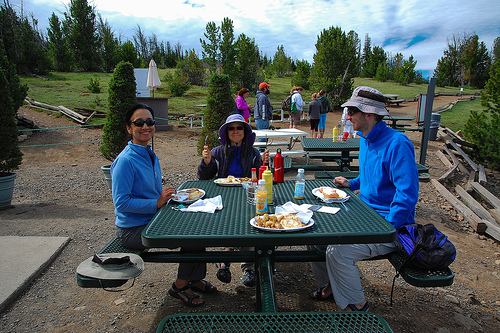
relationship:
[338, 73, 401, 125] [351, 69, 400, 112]
hat has stripe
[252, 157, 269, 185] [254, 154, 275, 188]
bottle of ketchup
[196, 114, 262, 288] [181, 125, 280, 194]
female has sweater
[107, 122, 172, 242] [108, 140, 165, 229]
man has jacket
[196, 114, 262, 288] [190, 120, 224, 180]
female holding fork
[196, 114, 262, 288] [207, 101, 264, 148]
female in hat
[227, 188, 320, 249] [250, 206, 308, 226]
plate has food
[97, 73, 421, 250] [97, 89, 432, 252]
people in clothes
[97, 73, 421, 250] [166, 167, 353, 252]
people eating meal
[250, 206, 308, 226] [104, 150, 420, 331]
food on table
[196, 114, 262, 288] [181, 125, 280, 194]
female has blue jacket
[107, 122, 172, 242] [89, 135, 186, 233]
man has jacket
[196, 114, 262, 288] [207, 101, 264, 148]
female has hat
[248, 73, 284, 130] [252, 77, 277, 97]
man has hat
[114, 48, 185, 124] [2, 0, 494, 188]
umbrella in background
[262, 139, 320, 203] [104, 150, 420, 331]
drinks on table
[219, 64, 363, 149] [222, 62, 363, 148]
six people standing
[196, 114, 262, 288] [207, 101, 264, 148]
female wearing hat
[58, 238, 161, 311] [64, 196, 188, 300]
hat on bench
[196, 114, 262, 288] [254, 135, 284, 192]
female holding knife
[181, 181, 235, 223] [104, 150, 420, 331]
napkin on table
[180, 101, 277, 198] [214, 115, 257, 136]
lady has sunglasses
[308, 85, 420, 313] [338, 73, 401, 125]
man has hat